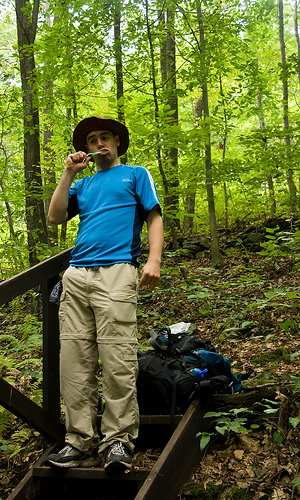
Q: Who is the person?
A: Boy.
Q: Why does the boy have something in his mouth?
A: Brushing teeth.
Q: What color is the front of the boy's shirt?
A: Blue.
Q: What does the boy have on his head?
A: Hat.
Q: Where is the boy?
A: Woods.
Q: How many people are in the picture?
A: 1.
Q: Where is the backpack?
A: Behind boy.